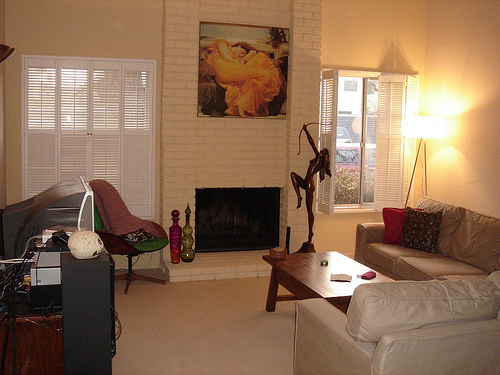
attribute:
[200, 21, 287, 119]
painting — large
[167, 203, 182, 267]
bottle — long, glass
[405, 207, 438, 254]
pillow — black, brown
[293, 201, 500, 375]
couch — leather, white color, white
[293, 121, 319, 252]
statue — bronze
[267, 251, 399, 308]
table — wooden, brown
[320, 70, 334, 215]
shutter — open, large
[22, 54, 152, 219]
shutters — closed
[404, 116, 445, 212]
lamp — on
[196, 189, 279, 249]
fireplace — open, unlit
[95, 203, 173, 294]
chair — green